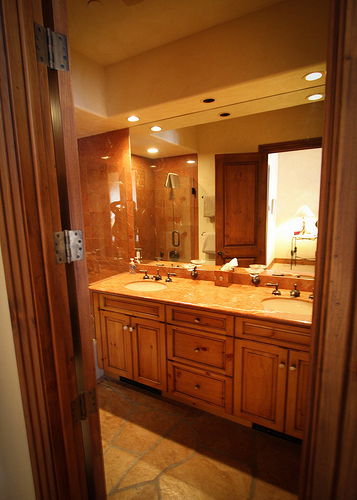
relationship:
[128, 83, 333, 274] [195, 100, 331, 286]
mirror on wall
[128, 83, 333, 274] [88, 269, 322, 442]
mirror above sink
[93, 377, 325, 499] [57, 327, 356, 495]
tile on floor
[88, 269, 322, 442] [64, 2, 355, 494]
his and her sink in bathroom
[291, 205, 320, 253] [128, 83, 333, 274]
lamp in mirror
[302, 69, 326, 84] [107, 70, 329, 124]
light on ceiling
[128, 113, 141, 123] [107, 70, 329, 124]
light on ceiling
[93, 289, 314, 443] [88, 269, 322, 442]
cabinet under sink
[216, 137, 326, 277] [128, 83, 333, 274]
door image in mirror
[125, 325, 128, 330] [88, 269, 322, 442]
knob on wood cabinet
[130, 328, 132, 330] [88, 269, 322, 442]
knob on wood cabinet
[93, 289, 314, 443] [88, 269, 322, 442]
drawers under sink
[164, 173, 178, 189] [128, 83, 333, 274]
towel on mirror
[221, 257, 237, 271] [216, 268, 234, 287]
tissue in box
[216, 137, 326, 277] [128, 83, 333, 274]
door on mirror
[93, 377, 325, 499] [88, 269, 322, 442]
tiles under sink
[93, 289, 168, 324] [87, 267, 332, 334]
drawer under counter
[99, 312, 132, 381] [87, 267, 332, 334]
drawer under counter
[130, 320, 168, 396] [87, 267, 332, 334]
drawer under counter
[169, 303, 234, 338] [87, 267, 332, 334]
drawer under counter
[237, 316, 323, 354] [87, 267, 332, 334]
drawer under counter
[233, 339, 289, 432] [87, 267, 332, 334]
drawer under counter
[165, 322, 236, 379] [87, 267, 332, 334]
drawer under counter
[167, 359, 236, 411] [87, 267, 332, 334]
drawer under counter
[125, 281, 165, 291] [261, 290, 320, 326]
sink next to sink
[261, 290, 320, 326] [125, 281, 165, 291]
sink on right of sink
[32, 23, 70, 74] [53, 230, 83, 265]
silver hinge on top of silver hinge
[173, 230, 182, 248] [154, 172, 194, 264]
handle on shower door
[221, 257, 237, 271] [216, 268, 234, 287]
tissues on box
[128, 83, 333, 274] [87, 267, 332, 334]
mirror above counter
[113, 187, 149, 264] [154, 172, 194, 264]
reflection in shower door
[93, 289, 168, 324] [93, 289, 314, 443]
drawer below cabinet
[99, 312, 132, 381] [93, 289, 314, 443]
drawer below cabinet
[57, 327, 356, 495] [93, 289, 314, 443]
floor under cabinet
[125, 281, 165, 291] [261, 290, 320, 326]
sink left of sink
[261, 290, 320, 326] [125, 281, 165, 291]
sink right of sink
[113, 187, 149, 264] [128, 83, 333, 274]
reflection in mirror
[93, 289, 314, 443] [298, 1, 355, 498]
cabinet left of door frame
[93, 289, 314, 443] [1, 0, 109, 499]
cabinet right of door frame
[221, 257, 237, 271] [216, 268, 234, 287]
tissues in box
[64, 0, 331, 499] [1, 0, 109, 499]
entry right of door frame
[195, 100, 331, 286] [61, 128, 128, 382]
wall next to bath tub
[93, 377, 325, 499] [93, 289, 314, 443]
floor under cabinet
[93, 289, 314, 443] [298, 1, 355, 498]
cabinet next to door frame